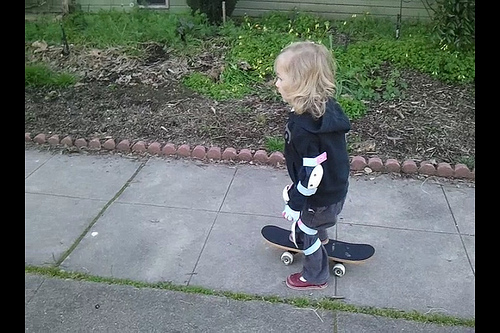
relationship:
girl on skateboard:
[271, 41, 352, 290] [259, 224, 373, 282]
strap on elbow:
[299, 150, 332, 166] [297, 166, 324, 193]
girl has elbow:
[271, 41, 352, 290] [297, 166, 324, 193]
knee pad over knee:
[288, 221, 301, 252] [292, 222, 319, 251]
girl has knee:
[271, 41, 352, 290] [292, 222, 319, 251]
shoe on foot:
[285, 270, 327, 291] [287, 268, 331, 294]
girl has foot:
[271, 41, 352, 290] [287, 268, 331, 294]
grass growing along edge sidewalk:
[25, 261, 478, 332] [26, 145, 475, 323]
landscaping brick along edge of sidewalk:
[147, 142, 161, 155] [26, 145, 475, 323]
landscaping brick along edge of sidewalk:
[165, 144, 175, 156] [26, 145, 475, 323]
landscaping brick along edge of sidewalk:
[177, 145, 190, 157] [26, 145, 475, 323]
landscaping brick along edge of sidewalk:
[195, 146, 207, 161] [26, 145, 475, 323]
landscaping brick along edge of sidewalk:
[209, 148, 224, 162] [26, 145, 475, 323]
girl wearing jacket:
[271, 41, 352, 290] [282, 113, 349, 206]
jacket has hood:
[282, 113, 349, 206] [295, 98, 350, 134]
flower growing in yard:
[235, 32, 255, 76] [25, 13, 478, 160]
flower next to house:
[344, 10, 368, 54] [23, 4, 475, 38]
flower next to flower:
[425, 31, 452, 77] [446, 47, 475, 86]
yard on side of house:
[25, 13, 478, 160] [23, 4, 475, 38]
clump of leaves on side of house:
[33, 34, 231, 88] [23, 4, 475, 38]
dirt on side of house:
[25, 66, 475, 165] [23, 4, 475, 38]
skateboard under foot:
[259, 224, 373, 282] [287, 268, 331, 294]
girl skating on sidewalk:
[271, 41, 352, 290] [26, 145, 475, 323]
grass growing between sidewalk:
[25, 261, 478, 332] [26, 145, 475, 323]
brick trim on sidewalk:
[25, 132, 477, 182] [26, 145, 475, 323]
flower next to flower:
[235, 32, 255, 76] [344, 10, 368, 54]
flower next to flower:
[446, 47, 475, 86] [425, 31, 452, 77]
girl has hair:
[271, 41, 352, 290] [276, 42, 338, 115]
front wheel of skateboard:
[281, 251, 295, 264] [259, 224, 373, 282]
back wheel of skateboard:
[333, 261, 347, 277] [259, 224, 373, 282]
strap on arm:
[299, 150, 332, 166] [283, 124, 324, 225]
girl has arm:
[271, 41, 352, 290] [283, 124, 324, 225]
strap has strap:
[299, 150, 332, 166] [299, 150, 332, 166]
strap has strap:
[293, 183, 318, 196] [293, 179, 318, 196]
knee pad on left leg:
[288, 221, 301, 252] [292, 199, 334, 283]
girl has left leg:
[271, 41, 352, 290] [292, 199, 334, 283]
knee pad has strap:
[288, 221, 301, 252] [295, 218, 321, 239]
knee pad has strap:
[288, 221, 301, 252] [301, 239, 322, 255]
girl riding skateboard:
[271, 41, 352, 290] [259, 224, 373, 282]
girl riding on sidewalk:
[271, 41, 352, 290] [26, 145, 475, 323]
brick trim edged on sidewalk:
[25, 132, 477, 182] [26, 145, 475, 323]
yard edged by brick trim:
[25, 13, 478, 160] [25, 132, 477, 182]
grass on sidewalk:
[25, 261, 478, 332] [26, 145, 475, 323]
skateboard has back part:
[259, 224, 373, 282] [325, 239, 373, 267]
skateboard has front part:
[259, 224, 373, 282] [261, 224, 303, 253]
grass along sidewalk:
[25, 261, 478, 332] [26, 145, 475, 323]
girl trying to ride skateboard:
[271, 41, 352, 290] [259, 224, 373, 282]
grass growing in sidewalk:
[25, 261, 478, 332] [26, 145, 475, 323]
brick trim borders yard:
[25, 132, 477, 182] [25, 13, 478, 160]